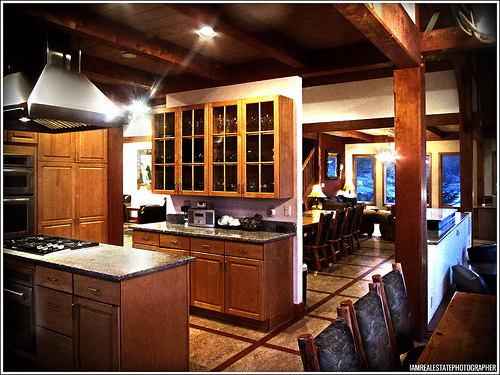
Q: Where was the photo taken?
A: It was taken at the kitchen.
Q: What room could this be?
A: It is a kitchen.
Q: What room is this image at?
A: It is at the kitchen.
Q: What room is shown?
A: It is a kitchen.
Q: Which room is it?
A: It is a kitchen.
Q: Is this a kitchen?
A: Yes, it is a kitchen.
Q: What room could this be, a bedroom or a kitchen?
A: It is a kitchen.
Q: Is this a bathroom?
A: No, it is a kitchen.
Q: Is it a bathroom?
A: No, it is a kitchen.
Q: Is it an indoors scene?
A: Yes, it is indoors.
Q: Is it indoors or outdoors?
A: It is indoors.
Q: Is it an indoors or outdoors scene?
A: It is indoors.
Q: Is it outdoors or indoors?
A: It is indoors.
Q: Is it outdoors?
A: No, it is indoors.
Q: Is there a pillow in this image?
A: No, there are no pillows.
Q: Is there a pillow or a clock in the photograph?
A: No, there are no pillows or clocks.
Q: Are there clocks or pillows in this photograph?
A: No, there are no pillows or clocks.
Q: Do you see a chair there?
A: Yes, there is a chair.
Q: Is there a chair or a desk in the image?
A: Yes, there is a chair.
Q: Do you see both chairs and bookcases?
A: No, there is a chair but no bookcases.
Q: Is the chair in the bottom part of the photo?
A: Yes, the chair is in the bottom of the image.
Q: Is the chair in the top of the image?
A: No, the chair is in the bottom of the image.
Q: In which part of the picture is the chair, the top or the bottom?
A: The chair is in the bottom of the image.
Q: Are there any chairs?
A: Yes, there is a chair.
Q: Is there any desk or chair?
A: Yes, there is a chair.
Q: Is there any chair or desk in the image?
A: Yes, there is a chair.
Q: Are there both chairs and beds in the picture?
A: No, there is a chair but no beds.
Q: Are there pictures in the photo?
A: No, there are no pictures.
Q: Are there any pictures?
A: No, there are no pictures.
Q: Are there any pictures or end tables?
A: No, there are no pictures or end tables.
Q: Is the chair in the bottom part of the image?
A: Yes, the chair is in the bottom of the image.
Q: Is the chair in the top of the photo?
A: No, the chair is in the bottom of the image.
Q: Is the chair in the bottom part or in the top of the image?
A: The chair is in the bottom of the image.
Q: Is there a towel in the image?
A: No, there are no towels.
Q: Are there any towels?
A: No, there are no towels.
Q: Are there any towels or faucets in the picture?
A: No, there are no towels or faucets.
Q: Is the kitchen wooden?
A: Yes, the kitchen is wooden.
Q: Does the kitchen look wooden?
A: Yes, the kitchen is wooden.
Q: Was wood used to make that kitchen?
A: Yes, the kitchen is made of wood.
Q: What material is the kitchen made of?
A: The kitchen is made of wood.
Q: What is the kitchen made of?
A: The kitchen is made of wood.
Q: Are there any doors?
A: Yes, there is a door.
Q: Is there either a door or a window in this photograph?
A: Yes, there is a door.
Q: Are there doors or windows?
A: Yes, there is a door.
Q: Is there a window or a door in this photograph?
A: Yes, there is a door.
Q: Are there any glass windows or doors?
A: Yes, there is a glass door.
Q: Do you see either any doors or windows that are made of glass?
A: Yes, the door is made of glass.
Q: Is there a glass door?
A: Yes, there is a door that is made of glass.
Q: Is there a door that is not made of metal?
A: Yes, there is a door that is made of glass.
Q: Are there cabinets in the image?
A: Yes, there is a cabinet.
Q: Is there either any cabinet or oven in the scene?
A: Yes, there is a cabinet.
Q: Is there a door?
A: Yes, there is a door.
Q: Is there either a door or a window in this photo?
A: Yes, there is a door.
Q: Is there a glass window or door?
A: Yes, there is a glass door.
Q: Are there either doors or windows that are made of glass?
A: Yes, the door is made of glass.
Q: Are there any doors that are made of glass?
A: Yes, there is a door that is made of glass.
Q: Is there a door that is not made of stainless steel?
A: Yes, there is a door that is made of glass.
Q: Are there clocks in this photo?
A: No, there are no clocks.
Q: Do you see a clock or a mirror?
A: No, there are no clocks or mirrors.